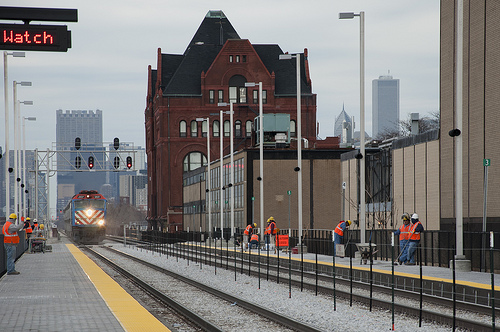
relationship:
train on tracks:
[56, 186, 108, 240] [108, 245, 205, 312]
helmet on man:
[6, 214, 23, 224] [2, 218, 29, 281]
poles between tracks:
[125, 226, 499, 330] [84, 240, 311, 328]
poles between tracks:
[125, 226, 499, 330] [194, 230, 496, 315]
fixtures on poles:
[336, 10, 360, 20] [196, 2, 479, 257]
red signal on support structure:
[88, 163, 95, 168] [29, 144, 146, 231]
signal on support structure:
[120, 152, 135, 169] [29, 144, 146, 231]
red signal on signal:
[87, 162, 95, 169] [127, 156, 133, 169]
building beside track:
[144, 10, 318, 233] [83, 227, 315, 330]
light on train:
[81, 206, 98, 218] [52, 185, 109, 244]